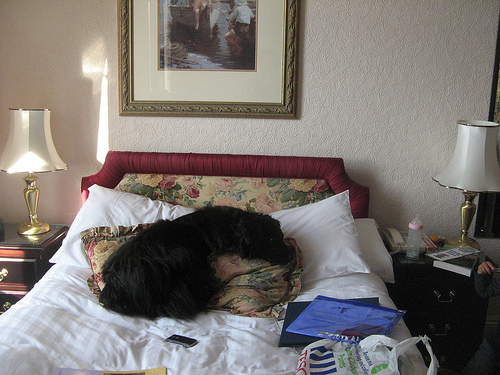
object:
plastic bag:
[298, 332, 441, 373]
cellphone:
[165, 334, 198, 348]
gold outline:
[9, 108, 52, 112]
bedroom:
[1, 0, 498, 374]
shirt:
[284, 292, 405, 347]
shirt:
[281, 280, 420, 362]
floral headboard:
[80, 151, 370, 220]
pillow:
[217, 189, 371, 284]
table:
[363, 37, 436, 97]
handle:
[425, 322, 450, 337]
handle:
[431, 292, 456, 304]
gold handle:
[426, 324, 453, 337]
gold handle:
[432, 290, 457, 303]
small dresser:
[391, 241, 494, 368]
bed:
[1, 147, 433, 373]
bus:
[78, 223, 306, 318]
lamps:
[431, 116, 498, 254]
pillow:
[47, 184, 198, 270]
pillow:
[283, 210, 368, 275]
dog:
[99, 206, 294, 320]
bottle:
[406, 214, 424, 261]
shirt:
[280, 282, 410, 347]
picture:
[116, 1, 305, 120]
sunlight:
[3, 103, 72, 203]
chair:
[410, 240, 496, 371]